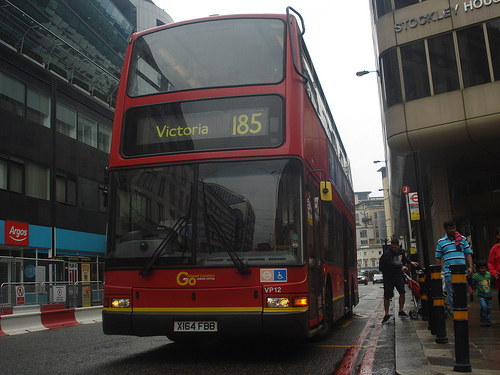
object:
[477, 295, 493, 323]
jeans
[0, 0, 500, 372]
large building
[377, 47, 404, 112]
tall window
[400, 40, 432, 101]
tall window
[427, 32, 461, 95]
tall window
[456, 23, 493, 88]
tall window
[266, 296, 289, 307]
headlight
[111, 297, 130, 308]
headlight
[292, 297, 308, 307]
turn light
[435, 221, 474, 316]
man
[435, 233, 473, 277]
shirt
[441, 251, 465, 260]
blue stripes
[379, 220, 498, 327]
people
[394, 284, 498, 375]
sidewalk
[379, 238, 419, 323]
man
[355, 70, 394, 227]
street light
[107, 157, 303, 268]
windshield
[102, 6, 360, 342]
bus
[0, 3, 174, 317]
wall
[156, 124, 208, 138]
sign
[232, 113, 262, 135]
victoria 185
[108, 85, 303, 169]
upper deck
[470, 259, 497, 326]
boy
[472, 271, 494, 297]
t shirt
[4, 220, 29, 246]
company logo